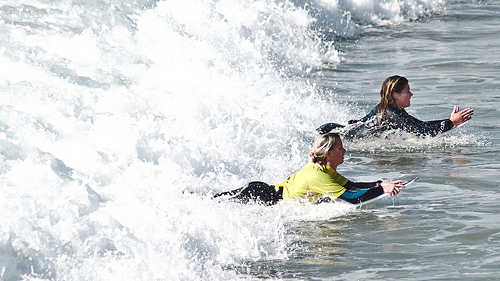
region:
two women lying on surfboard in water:
[197, 76, 488, 236]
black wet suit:
[296, 96, 455, 151]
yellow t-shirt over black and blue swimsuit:
[213, 153, 384, 218]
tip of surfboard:
[340, 168, 428, 210]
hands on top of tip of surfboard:
[429, 99, 483, 136]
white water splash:
[110, 21, 267, 156]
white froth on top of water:
[426, 202, 495, 236]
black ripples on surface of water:
[417, 44, 497, 80]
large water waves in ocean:
[3, 0, 456, 278]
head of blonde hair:
[305, 132, 350, 171]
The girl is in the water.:
[286, 56, 481, 151]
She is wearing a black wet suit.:
[300, 76, 453, 143]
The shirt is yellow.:
[273, 161, 355, 216]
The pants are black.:
[210, 177, 282, 216]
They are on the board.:
[223, 38, 487, 250]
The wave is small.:
[14, 12, 335, 271]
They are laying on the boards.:
[202, 56, 479, 233]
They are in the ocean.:
[191, 45, 469, 280]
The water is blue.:
[329, 0, 493, 275]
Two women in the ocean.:
[0, 7, 489, 272]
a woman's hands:
[377, 174, 408, 199]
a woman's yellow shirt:
[273, 157, 340, 207]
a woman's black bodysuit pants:
[203, 178, 286, 205]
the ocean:
[0, 0, 497, 279]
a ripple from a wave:
[373, 43, 438, 57]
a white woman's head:
[380, 75, 414, 107]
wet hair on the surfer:
[372, 74, 410, 115]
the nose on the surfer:
[406, 93, 413, 98]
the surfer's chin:
[403, 101, 412, 107]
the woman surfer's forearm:
[344, 178, 384, 201]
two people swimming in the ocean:
[224, 85, 465, 220]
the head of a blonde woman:
[307, 138, 345, 173]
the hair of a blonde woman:
[300, 142, 332, 179]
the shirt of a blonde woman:
[285, 171, 339, 208]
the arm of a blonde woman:
[341, 166, 366, 216]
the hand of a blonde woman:
[377, 171, 395, 205]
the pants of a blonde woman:
[205, 168, 273, 210]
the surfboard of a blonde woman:
[330, 181, 415, 216]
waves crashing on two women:
[145, 79, 240, 201]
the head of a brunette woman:
[377, 63, 409, 111]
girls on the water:
[222, 34, 491, 235]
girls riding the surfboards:
[167, 37, 473, 232]